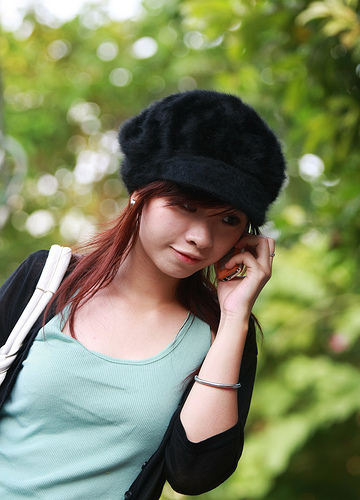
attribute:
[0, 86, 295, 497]
girl — young, asian, attractive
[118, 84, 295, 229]
hat — black, furry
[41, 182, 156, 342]
hair — red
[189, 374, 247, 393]
bracelet — silver, metal, gray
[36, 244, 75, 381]
strap — white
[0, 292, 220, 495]
shirt — turquoise, green, blue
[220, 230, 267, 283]
cellphone — orange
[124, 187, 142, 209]
earring — diamond, gold, silver, bright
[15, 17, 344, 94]
trees — green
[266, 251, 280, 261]
ring — silver